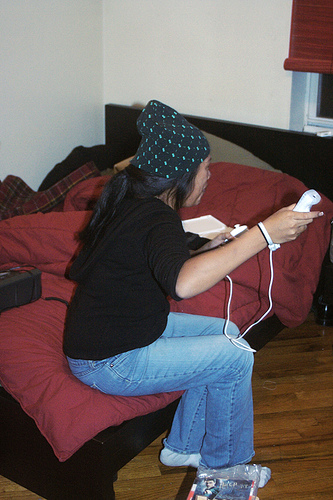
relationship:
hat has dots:
[134, 94, 214, 176] [156, 127, 167, 144]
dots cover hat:
[156, 127, 167, 144] [134, 94, 214, 176]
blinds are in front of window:
[287, 3, 331, 74] [283, 1, 330, 132]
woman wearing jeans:
[63, 99, 325, 500] [67, 316, 257, 461]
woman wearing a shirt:
[63, 99, 325, 500] [68, 190, 183, 361]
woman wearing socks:
[63, 99, 325, 500] [152, 445, 273, 487]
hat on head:
[134, 94, 214, 176] [126, 100, 213, 211]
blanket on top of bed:
[2, 161, 332, 456] [1, 93, 329, 493]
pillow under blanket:
[215, 133, 275, 168] [2, 161, 332, 456]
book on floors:
[185, 468, 242, 500] [12, 327, 332, 500]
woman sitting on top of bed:
[63, 99, 325, 500] [1, 93, 329, 493]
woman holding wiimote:
[63, 99, 325, 500] [224, 181, 324, 262]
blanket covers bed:
[2, 161, 332, 456] [1, 93, 329, 493]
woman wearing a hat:
[63, 99, 325, 500] [134, 94, 214, 176]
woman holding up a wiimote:
[63, 99, 325, 500] [224, 181, 324, 262]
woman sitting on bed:
[63, 99, 325, 500] [1, 93, 329, 493]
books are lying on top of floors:
[185, 468, 242, 500] [12, 327, 332, 500]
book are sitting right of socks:
[185, 468, 256, 500] [152, 445, 273, 487]